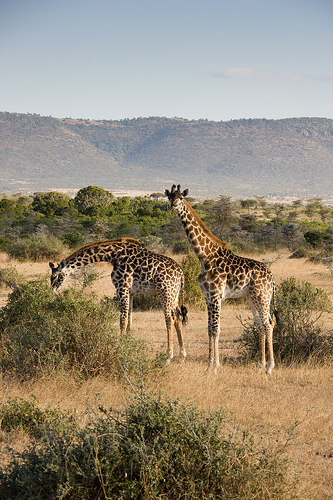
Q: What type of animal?
A: Two giraffes.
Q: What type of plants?
A: Shrubs on prairie.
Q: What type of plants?
A: Shrubs on prairie.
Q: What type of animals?
A: Two giraffes.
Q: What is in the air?
A: Cloud in sky.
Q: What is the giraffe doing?
A: Eating grass.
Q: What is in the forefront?
A: Brown grass.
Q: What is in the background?
A: Mountains.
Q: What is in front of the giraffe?
A: A bush.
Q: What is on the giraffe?
A: Brown spots.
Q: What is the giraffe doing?
A: Eating a bush.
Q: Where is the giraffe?
A: In the savannah.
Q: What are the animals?
A: Giraffes.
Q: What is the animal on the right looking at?
A: Camera.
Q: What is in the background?
A: Hills.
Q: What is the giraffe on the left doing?
A: Eating.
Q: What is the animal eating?
A: Grass.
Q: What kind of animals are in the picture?
A: Giraffe.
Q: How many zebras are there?
A: Two.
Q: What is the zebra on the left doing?
A: Eating.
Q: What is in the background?
A: Mountains.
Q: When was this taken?
A: Daytime.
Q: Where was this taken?
A: In the wild.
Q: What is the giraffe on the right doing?
A: Looking at the camera.